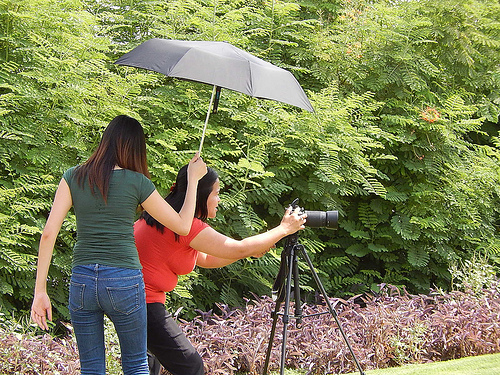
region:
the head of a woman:
[65, 111, 139, 197]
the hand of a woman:
[24, 294, 56, 329]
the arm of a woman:
[17, 163, 109, 321]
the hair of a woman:
[70, 109, 145, 191]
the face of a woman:
[203, 162, 244, 217]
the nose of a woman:
[204, 195, 237, 215]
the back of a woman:
[64, 145, 164, 290]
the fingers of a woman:
[275, 207, 310, 239]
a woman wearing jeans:
[70, 239, 203, 354]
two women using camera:
[2, 17, 490, 374]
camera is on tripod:
[243, 150, 403, 372]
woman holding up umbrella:
[20, 11, 316, 373]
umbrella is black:
[103, 17, 322, 247]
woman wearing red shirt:
[128, 199, 213, 325]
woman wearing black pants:
[103, 271, 213, 373]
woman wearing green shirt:
[55, 145, 160, 275]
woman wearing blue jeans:
[58, 246, 163, 373]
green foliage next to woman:
[0, 0, 487, 307]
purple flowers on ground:
[8, 269, 495, 370]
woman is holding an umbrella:
[110, 13, 326, 199]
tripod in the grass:
[271, 232, 362, 374]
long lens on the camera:
[286, 201, 343, 230]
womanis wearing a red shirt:
[122, 181, 217, 315]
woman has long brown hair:
[60, 98, 168, 201]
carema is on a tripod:
[249, 187, 379, 373]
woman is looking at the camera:
[179, 162, 257, 253]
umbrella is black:
[93, 29, 337, 126]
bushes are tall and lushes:
[3, 2, 496, 307]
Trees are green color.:
[351, 46, 457, 170]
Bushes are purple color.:
[198, 308, 456, 363]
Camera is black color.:
[268, 191, 353, 251]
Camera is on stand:
[273, 198, 342, 313]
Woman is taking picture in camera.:
[151, 162, 334, 348]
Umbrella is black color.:
[75, 30, 337, 125]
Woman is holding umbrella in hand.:
[45, 35, 173, 353]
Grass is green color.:
[410, 355, 497, 373]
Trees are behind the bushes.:
[69, 45, 480, 372]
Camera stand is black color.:
[256, 198, 374, 373]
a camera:
[273, 199, 373, 373]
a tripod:
[259, 245, 361, 372]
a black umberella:
[118, 38, 315, 113]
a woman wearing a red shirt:
[143, 165, 231, 362]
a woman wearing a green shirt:
[48, 116, 172, 373]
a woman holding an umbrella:
[61, 40, 307, 362]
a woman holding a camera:
[158, 165, 333, 253]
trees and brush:
[320, 44, 482, 280]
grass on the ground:
[389, 354, 489, 373]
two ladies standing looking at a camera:
[39, 123, 299, 333]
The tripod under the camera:
[261, 244, 363, 374]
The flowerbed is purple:
[176, 277, 498, 374]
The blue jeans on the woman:
[68, 263, 149, 373]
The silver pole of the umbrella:
[196, 82, 217, 158]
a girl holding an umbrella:
[30, 114, 207, 374]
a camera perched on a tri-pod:
[274, 205, 342, 237]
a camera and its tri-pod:
[259, 207, 368, 373]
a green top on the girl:
[62, 162, 154, 267]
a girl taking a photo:
[133, 164, 308, 374]